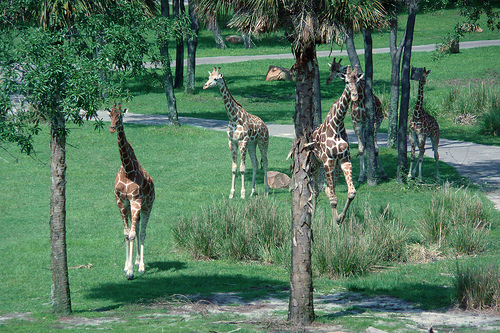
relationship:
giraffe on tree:
[301, 67, 368, 238] [203, 1, 393, 320]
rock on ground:
[262, 167, 298, 193] [11, 8, 497, 327]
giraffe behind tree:
[104, 99, 155, 280] [3, 2, 199, 313]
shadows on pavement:
[440, 157, 498, 191] [3, 86, 496, 206]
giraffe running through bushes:
[282, 63, 367, 227] [170, 176, 500, 316]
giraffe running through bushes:
[104, 99, 155, 280] [173, 173, 496, 318]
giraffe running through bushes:
[312, 67, 357, 224] [360, 215, 380, 267]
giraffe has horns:
[197, 63, 274, 200] [210, 62, 225, 73]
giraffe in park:
[99, 104, 159, 281] [5, 1, 495, 330]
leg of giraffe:
[336, 152, 356, 223] [312, 64, 365, 227]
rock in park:
[265, 65, 295, 81] [5, 1, 495, 330]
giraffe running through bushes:
[312, 64, 365, 227] [376, 190, 446, 251]